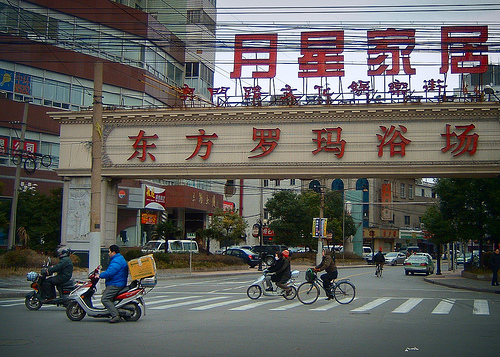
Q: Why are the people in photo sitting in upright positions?
A: Riding vehicles.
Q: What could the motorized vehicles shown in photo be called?
A: Mopeds.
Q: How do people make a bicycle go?
A: By pedaling.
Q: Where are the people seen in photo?
A: Street.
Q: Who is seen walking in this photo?
A: No One.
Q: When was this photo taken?
A: Daytime.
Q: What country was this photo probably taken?
A: China.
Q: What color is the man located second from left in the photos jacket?
A: Blue.